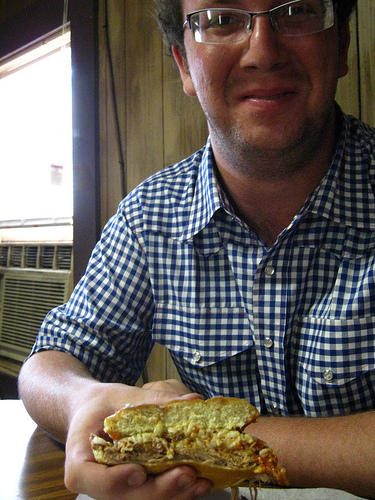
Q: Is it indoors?
A: Yes, it is indoors.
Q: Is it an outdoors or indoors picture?
A: It is indoors.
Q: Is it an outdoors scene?
A: No, it is indoors.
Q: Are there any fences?
A: No, there are no fences.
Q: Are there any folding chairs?
A: No, there are no folding chairs.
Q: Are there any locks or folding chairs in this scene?
A: No, there are no folding chairs or locks.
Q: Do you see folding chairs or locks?
A: No, there are no folding chairs or locks.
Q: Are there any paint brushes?
A: No, there are no paint brushes.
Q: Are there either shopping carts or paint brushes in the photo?
A: No, there are no paint brushes or shopping carts.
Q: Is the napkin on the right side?
A: Yes, the napkin is on the right of the image.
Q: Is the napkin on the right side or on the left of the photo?
A: The napkin is on the right of the image.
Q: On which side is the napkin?
A: The napkin is on the right of the image.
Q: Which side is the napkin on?
A: The napkin is on the right of the image.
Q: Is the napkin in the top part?
A: No, the napkin is in the bottom of the image.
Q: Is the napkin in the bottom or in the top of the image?
A: The napkin is in the bottom of the image.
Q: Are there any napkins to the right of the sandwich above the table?
A: Yes, there is a napkin to the right of the sandwich.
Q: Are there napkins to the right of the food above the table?
A: Yes, there is a napkin to the right of the sandwich.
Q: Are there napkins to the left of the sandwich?
A: No, the napkin is to the right of the sandwich.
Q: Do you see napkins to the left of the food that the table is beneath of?
A: No, the napkin is to the right of the sandwich.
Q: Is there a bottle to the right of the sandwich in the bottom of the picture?
A: No, there is a napkin to the right of the sandwich.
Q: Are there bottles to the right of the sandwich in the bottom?
A: No, there is a napkin to the right of the sandwich.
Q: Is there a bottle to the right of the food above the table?
A: No, there is a napkin to the right of the sandwich.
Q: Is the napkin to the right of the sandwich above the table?
A: Yes, the napkin is to the right of the sandwich.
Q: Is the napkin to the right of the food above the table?
A: Yes, the napkin is to the right of the sandwich.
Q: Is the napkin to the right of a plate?
A: No, the napkin is to the right of the sandwich.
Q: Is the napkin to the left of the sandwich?
A: No, the napkin is to the right of the sandwich.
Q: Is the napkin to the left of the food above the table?
A: No, the napkin is to the right of the sandwich.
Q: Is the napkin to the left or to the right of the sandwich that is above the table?
A: The napkin is to the right of the sandwich.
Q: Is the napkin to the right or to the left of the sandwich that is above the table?
A: The napkin is to the right of the sandwich.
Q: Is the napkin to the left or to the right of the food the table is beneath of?
A: The napkin is to the right of the sandwich.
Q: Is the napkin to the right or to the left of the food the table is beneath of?
A: The napkin is to the right of the sandwich.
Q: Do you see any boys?
A: No, there are no boys.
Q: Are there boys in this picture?
A: No, there are no boys.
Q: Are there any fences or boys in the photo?
A: No, there are no boys or fences.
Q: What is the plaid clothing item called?
A: The clothing item is a shirt.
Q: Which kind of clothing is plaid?
A: The clothing is a shirt.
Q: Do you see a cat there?
A: No, there are no cats.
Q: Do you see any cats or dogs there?
A: No, there are no cats or dogs.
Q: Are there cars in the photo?
A: No, there are no cars.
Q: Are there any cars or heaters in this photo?
A: No, there are no cars or heaters.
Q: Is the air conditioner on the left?
A: Yes, the air conditioner is on the left of the image.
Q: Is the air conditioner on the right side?
A: No, the air conditioner is on the left of the image.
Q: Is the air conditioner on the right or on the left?
A: The air conditioner is on the left of the image.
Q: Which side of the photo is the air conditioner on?
A: The air conditioner is on the left of the image.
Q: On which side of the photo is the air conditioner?
A: The air conditioner is on the left of the image.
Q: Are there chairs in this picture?
A: No, there are no chairs.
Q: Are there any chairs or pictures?
A: No, there are no chairs or pictures.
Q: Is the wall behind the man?
A: Yes, the wall is behind the man.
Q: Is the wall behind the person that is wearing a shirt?
A: Yes, the wall is behind the man.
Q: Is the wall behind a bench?
A: No, the wall is behind the man.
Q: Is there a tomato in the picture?
A: Yes, there is a tomato.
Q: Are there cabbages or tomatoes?
A: Yes, there is a tomato.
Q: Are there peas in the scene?
A: No, there are no peas.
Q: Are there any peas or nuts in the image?
A: No, there are no peas or nuts.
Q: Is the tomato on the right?
A: Yes, the tomato is on the right of the image.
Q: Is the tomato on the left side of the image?
A: No, the tomato is on the right of the image.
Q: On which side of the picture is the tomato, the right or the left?
A: The tomato is on the right of the image.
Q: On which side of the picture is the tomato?
A: The tomato is on the right of the image.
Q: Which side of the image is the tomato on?
A: The tomato is on the right of the image.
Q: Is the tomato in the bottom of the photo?
A: Yes, the tomato is in the bottom of the image.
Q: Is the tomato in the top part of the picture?
A: No, the tomato is in the bottom of the image.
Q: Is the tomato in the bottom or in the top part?
A: The tomato is in the bottom of the image.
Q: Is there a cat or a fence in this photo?
A: No, there are no fences or cats.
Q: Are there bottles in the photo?
A: No, there are no bottles.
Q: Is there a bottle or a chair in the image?
A: No, there are no bottles or chairs.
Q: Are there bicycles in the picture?
A: No, there are no bicycles.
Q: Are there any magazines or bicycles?
A: No, there are no bicycles or magazines.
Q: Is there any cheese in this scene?
A: Yes, there is cheese.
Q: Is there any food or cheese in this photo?
A: Yes, there is cheese.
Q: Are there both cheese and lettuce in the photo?
A: No, there is cheese but no lettuce.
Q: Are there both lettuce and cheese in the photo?
A: No, there is cheese but no lettuce.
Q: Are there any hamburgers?
A: No, there are no hamburgers.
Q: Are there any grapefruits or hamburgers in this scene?
A: No, there are no hamburgers or grapefruits.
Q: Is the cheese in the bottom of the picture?
A: Yes, the cheese is in the bottom of the image.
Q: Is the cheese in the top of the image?
A: No, the cheese is in the bottom of the image.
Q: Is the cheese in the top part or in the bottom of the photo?
A: The cheese is in the bottom of the image.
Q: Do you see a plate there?
A: No, there are no plates.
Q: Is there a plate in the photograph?
A: No, there are no plates.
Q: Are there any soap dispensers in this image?
A: No, there are no soap dispensers.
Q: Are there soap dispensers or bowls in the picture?
A: No, there are no soap dispensers or bowls.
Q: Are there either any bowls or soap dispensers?
A: No, there are no soap dispensers or bowls.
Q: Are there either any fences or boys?
A: No, there are no fences or boys.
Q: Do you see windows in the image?
A: Yes, there is a window.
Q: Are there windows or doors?
A: Yes, there is a window.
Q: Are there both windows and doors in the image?
A: No, there is a window but no doors.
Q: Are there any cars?
A: No, there are no cars.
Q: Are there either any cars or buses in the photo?
A: No, there are no cars or buses.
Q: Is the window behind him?
A: Yes, the window is behind a man.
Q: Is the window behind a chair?
A: No, the window is behind a man.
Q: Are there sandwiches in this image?
A: Yes, there is a sandwich.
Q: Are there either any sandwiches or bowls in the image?
A: Yes, there is a sandwich.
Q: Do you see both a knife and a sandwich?
A: No, there is a sandwich but no knives.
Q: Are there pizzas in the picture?
A: No, there are no pizzas.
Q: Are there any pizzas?
A: No, there are no pizzas.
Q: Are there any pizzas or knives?
A: No, there are no pizzas or knives.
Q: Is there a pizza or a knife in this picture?
A: No, there are no pizzas or knives.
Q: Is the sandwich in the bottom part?
A: Yes, the sandwich is in the bottom of the image.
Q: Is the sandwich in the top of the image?
A: No, the sandwich is in the bottom of the image.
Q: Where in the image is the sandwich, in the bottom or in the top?
A: The sandwich is in the bottom of the image.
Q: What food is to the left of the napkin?
A: The food is a sandwich.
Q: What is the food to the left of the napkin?
A: The food is a sandwich.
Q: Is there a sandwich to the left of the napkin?
A: Yes, there is a sandwich to the left of the napkin.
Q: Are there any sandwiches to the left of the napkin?
A: Yes, there is a sandwich to the left of the napkin.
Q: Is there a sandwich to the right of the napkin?
A: No, the sandwich is to the left of the napkin.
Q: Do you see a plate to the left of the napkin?
A: No, there is a sandwich to the left of the napkin.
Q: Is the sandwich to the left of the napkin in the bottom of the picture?
A: Yes, the sandwich is to the left of the napkin.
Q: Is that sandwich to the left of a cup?
A: No, the sandwich is to the left of the napkin.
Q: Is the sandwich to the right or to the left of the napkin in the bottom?
A: The sandwich is to the left of the napkin.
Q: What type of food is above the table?
A: The food is a sandwich.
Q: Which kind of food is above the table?
A: The food is a sandwich.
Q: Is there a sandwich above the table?
A: Yes, there is a sandwich above the table.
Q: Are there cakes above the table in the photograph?
A: No, there is a sandwich above the table.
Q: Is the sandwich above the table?
A: Yes, the sandwich is above the table.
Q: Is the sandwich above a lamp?
A: No, the sandwich is above the table.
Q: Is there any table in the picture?
A: Yes, there is a table.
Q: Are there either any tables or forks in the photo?
A: Yes, there is a table.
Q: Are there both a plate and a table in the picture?
A: No, there is a table but no plates.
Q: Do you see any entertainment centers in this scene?
A: No, there are no entertainment centers.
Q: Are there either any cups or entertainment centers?
A: No, there are no entertainment centers or cups.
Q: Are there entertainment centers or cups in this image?
A: No, there are no entertainment centers or cups.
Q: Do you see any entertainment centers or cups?
A: No, there are no entertainment centers or cups.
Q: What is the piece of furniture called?
A: The piece of furniture is a table.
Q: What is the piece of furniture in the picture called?
A: The piece of furniture is a table.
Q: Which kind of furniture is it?
A: The piece of furniture is a table.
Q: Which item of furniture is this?
A: This is a table.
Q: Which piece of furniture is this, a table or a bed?
A: This is a table.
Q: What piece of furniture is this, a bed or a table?
A: This is a table.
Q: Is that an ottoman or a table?
A: That is a table.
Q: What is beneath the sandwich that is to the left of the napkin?
A: The table is beneath the sandwich.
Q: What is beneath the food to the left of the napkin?
A: The table is beneath the sandwich.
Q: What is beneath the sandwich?
A: The table is beneath the sandwich.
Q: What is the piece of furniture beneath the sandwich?
A: The piece of furniture is a table.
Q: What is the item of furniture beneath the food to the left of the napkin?
A: The piece of furniture is a table.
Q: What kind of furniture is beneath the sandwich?
A: The piece of furniture is a table.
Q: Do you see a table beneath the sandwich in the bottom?
A: Yes, there is a table beneath the sandwich.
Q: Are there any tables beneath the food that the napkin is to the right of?
A: Yes, there is a table beneath the sandwich.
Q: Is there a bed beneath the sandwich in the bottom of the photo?
A: No, there is a table beneath the sandwich.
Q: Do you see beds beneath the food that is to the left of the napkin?
A: No, there is a table beneath the sandwich.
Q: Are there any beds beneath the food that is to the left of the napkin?
A: No, there is a table beneath the sandwich.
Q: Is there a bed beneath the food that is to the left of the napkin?
A: No, there is a table beneath the sandwich.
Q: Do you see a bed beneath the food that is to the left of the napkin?
A: No, there is a table beneath the sandwich.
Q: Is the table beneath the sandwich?
A: Yes, the table is beneath the sandwich.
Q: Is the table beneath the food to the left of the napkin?
A: Yes, the table is beneath the sandwich.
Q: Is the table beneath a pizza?
A: No, the table is beneath the sandwich.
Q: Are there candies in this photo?
A: No, there are no candies.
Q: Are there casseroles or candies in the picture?
A: No, there are no candies or casseroles.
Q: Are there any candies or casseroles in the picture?
A: No, there are no candies or casseroles.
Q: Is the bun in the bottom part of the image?
A: Yes, the bun is in the bottom of the image.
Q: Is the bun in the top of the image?
A: No, the bun is in the bottom of the image.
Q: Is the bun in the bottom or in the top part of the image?
A: The bun is in the bottom of the image.